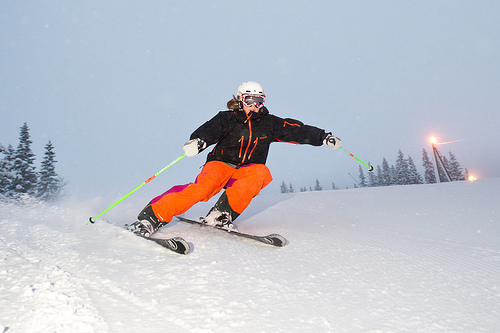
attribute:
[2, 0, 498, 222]
sky — blue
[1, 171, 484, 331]
snow — fresh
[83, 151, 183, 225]
ski pole — lime green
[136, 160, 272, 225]
pants — orange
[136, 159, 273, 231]
pants — orange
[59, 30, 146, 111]
clouds — white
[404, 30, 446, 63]
clouds — white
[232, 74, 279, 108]
helmet — white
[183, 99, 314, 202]
shirt — black, red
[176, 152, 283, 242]
pants — orange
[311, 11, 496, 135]
sky — hazy, blue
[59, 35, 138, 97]
clouds — white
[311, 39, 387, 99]
clouds — white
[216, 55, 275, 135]
pant — orange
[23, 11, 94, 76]
sky — blue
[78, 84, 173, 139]
sky — blue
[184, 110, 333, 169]
jacket — black, orange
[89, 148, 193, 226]
pole — ski pole, green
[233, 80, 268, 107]
helmet — ski helmet, white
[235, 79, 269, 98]
helmet — white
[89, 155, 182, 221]
ski pole — green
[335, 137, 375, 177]
ski pole — green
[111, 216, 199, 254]
ski — black, gray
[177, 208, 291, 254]
ski — black, gray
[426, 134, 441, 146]
light — bright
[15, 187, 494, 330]
snow — white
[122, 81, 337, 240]
person — dressed